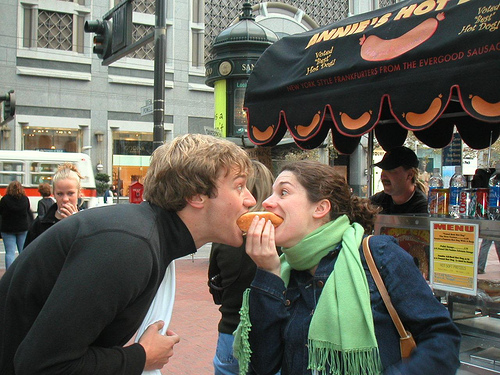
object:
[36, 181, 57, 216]
people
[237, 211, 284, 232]
food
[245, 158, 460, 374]
girl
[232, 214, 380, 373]
scarf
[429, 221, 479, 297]
menu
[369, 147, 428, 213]
man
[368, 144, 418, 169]
hat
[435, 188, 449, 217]
drinks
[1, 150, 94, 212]
vehicle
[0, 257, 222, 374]
ground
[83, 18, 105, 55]
traffic light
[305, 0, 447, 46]
annie's hot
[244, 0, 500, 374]
stand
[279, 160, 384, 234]
hair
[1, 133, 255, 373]
man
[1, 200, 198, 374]
turtleneck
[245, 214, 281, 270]
hand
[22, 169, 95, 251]
female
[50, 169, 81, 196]
blonde hair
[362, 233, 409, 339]
strap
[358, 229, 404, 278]
shoulder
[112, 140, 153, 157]
sign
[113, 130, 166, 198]
store window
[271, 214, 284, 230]
mouth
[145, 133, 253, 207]
hair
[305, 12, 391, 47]
annie's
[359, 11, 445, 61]
hot dog graphic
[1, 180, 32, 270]
woman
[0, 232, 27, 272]
jeans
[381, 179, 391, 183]
mustache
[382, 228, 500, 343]
window